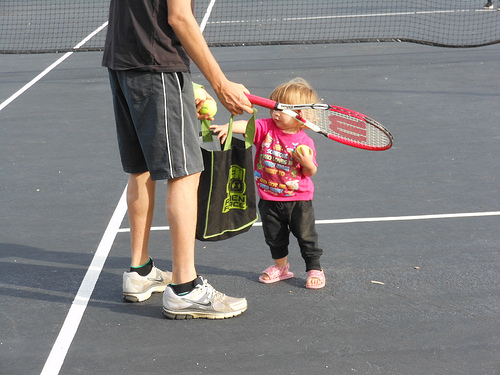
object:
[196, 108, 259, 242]
bag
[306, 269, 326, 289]
pink shoes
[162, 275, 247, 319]
foot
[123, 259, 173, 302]
foot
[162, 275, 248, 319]
shoe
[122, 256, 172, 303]
shoe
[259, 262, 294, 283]
shoes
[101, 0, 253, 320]
dad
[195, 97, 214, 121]
hand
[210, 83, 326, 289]
baby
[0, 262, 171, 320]
shadow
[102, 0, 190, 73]
black shirt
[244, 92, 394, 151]
racket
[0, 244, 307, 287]
shadow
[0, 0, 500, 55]
net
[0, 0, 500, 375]
field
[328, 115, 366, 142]
w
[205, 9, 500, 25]
lines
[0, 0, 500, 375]
court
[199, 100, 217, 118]
ball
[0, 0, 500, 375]
picture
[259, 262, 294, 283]
chappel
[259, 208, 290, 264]
leg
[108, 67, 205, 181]
black shorts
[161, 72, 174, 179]
stripes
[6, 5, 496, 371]
ground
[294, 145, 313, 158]
tennis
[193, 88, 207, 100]
balls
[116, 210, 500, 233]
line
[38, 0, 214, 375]
line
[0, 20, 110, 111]
line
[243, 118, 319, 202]
shirt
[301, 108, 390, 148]
strings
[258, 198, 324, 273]
pants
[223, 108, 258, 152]
handles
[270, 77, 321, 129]
hair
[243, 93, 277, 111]
handle